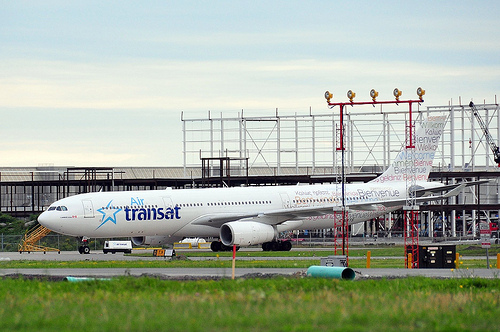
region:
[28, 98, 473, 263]
a white plane on a landing lane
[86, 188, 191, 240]
blue letters on a plane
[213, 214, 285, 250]
an engine in front a wing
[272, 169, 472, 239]
wing on the right side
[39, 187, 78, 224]
windows of cockpit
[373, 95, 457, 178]
letters on a vertical stabilizer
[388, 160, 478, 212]
tip of a plane wing is curved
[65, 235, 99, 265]
front wheels of plane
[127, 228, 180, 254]
engine on left side of plane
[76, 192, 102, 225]
door on side of plane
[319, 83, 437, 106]
Runway lights at an airport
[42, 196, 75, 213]
Flight deck of a passenger jet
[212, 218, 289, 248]
Engine of a passenger jet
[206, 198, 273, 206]
Windows on the side of a passenger jet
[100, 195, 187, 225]
Logo on the side of a passenger jet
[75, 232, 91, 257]
Front landing gear on a passenger jet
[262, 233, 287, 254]
Rear landing gear on a passenger jet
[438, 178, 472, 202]
Angled wingtip on a passenger jet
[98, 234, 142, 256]
Utility trailer at an airport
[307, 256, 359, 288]
Piece of pipe laying on the ground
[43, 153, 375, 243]
this is a plane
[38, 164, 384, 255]
the plane is parked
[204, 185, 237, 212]
the plane is white in color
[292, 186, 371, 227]
this is the wing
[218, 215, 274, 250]
this is the propeller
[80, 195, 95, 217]
the door is closed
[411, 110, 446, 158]
this is the tail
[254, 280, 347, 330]
the grass is green in color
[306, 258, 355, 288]
this is a pipe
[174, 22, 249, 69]
the sky is blue in color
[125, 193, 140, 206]
word air is written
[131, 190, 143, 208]
word air is written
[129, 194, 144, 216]
word air is written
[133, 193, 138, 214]
word air is written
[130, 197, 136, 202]
word air is written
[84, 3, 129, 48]
part of the sky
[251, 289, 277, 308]
part of some grass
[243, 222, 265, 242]
part of an engine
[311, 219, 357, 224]
part of a metal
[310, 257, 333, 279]
edge of a pipe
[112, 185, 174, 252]
ide of a plane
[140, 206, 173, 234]
part of a graphic